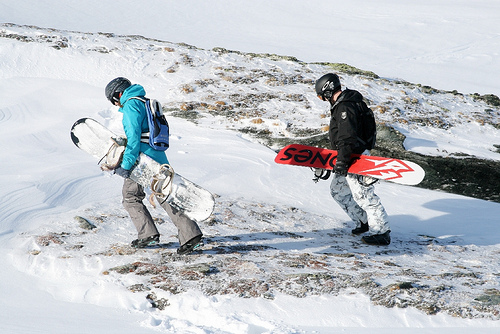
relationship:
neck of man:
[326, 91, 345, 102] [305, 68, 392, 245]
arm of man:
[332, 106, 358, 180] [305, 68, 392, 245]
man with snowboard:
[315, 71, 394, 246] [278, 125, 427, 193]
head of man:
[314, 72, 339, 104] [315, 71, 394, 246]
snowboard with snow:
[74, 122, 218, 224] [0, 177, 492, 332]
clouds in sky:
[407, 20, 483, 63] [2, 1, 499, 97]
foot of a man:
[357, 228, 393, 248] [315, 71, 394, 246]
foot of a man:
[348, 221, 370, 236] [315, 71, 394, 246]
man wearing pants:
[315, 71, 394, 246] [271, 138, 426, 190]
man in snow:
[314, 63, 398, 256] [7, 54, 55, 196]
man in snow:
[104, 77, 202, 254] [7, 54, 55, 196]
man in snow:
[104, 77, 205, 253] [2, 21, 484, 331]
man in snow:
[315, 71, 394, 246] [2, 21, 484, 331]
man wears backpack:
[104, 77, 205, 253] [139, 91, 182, 154]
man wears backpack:
[315, 71, 394, 246] [348, 87, 385, 156]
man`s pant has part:
[121, 177, 203, 244] [124, 197, 149, 224]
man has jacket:
[104, 77, 202, 254] [120, 85, 169, 167]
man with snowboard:
[104, 77, 205, 253] [80, 124, 214, 214]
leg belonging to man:
[345, 162, 394, 247] [315, 71, 394, 246]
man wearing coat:
[315, 71, 394, 246] [326, 86, 372, 166]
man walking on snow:
[104, 77, 205, 253] [2, 21, 484, 331]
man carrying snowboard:
[315, 71, 394, 246] [272, 139, 426, 188]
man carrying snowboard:
[104, 77, 205, 253] [68, 116, 215, 226]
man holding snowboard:
[104, 77, 205, 253] [66, 110, 221, 230]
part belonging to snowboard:
[67, 115, 88, 146] [68, 116, 215, 226]